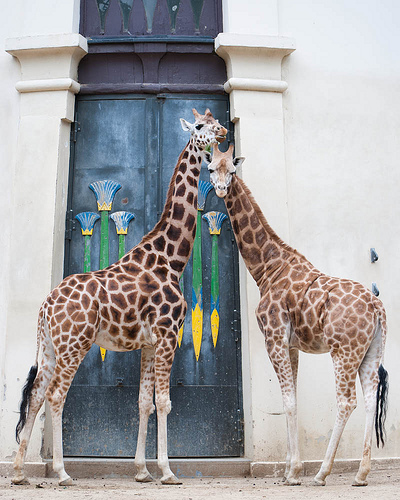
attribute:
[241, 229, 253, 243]
spot — brown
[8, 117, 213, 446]
giraffe — brown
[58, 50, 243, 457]
door —  front 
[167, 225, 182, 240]
spot — brown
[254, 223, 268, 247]
spot — brown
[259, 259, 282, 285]
spot — brown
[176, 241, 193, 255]
spot — brown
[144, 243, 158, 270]
spot — brown